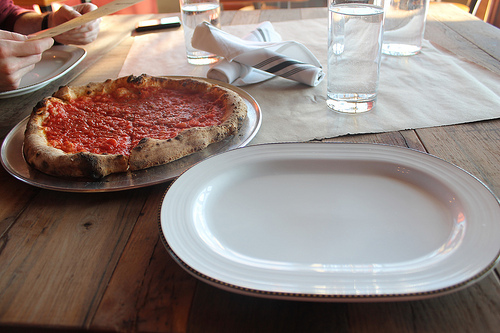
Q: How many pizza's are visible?
A: One.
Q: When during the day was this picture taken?
A: Daytime.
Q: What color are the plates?
A: White.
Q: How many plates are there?
A: Two.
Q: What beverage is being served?
A: Water.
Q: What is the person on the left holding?
A: Menu.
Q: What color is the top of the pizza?
A: Red.